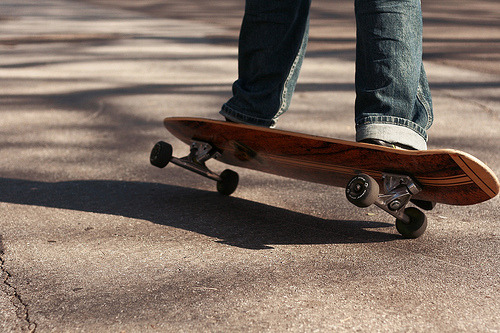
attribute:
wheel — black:
[150, 141, 173, 167]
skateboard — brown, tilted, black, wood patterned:
[160, 116, 500, 214]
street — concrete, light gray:
[3, 5, 491, 332]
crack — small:
[1, 253, 34, 332]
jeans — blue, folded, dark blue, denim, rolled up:
[243, 2, 434, 156]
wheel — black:
[215, 171, 238, 192]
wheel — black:
[349, 174, 374, 203]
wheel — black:
[400, 208, 427, 238]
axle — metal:
[174, 138, 220, 186]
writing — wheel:
[356, 177, 370, 186]